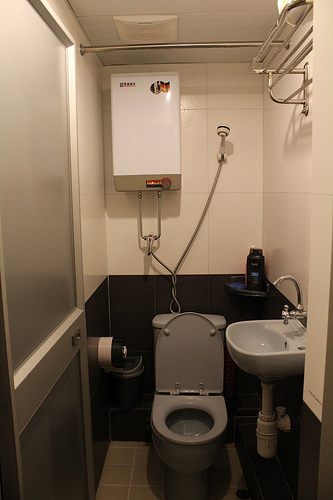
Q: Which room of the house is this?
A: It is a bathroom.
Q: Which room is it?
A: It is a bathroom.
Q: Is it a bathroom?
A: Yes, it is a bathroom.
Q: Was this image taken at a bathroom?
A: Yes, it was taken in a bathroom.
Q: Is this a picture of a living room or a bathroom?
A: It is showing a bathroom.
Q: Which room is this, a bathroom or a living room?
A: It is a bathroom.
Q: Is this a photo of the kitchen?
A: No, the picture is showing the bathroom.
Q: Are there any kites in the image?
A: No, there are no kites.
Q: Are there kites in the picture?
A: No, there are no kites.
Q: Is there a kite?
A: No, there are no kites.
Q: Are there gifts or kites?
A: No, there are no kites or gifts.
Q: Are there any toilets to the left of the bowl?
A: Yes, there is a toilet to the left of the bowl.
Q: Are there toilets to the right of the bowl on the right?
A: No, the toilet is to the left of the bowl.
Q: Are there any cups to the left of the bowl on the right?
A: No, there is a toilet to the left of the bowl.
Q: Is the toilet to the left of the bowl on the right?
A: Yes, the toilet is to the left of the bowl.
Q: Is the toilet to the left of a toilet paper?
A: No, the toilet is to the left of the bowl.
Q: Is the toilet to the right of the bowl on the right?
A: No, the toilet is to the left of the bowl.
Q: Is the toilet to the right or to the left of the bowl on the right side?
A: The toilet is to the left of the bowl.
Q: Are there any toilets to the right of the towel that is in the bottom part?
A: Yes, there is a toilet to the right of the towel.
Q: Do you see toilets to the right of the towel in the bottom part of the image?
A: Yes, there is a toilet to the right of the towel.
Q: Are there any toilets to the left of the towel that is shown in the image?
A: No, the toilet is to the right of the towel.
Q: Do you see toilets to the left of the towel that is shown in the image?
A: No, the toilet is to the right of the towel.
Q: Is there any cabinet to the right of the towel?
A: No, there is a toilet to the right of the towel.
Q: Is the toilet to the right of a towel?
A: Yes, the toilet is to the right of a towel.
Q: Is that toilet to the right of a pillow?
A: No, the toilet is to the right of a towel.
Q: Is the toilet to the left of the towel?
A: No, the toilet is to the right of the towel.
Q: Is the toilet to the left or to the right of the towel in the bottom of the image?
A: The toilet is to the right of the towel.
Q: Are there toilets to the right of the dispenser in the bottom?
A: Yes, there is a toilet to the right of the dispenser.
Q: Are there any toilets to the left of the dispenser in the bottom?
A: No, the toilet is to the right of the dispenser.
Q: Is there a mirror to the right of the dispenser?
A: No, there is a toilet to the right of the dispenser.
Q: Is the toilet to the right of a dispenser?
A: Yes, the toilet is to the right of a dispenser.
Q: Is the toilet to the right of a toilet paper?
A: No, the toilet is to the right of a dispenser.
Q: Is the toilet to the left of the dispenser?
A: No, the toilet is to the right of the dispenser.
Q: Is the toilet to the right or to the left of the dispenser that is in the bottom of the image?
A: The toilet is to the right of the dispenser.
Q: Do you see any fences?
A: No, there are no fences.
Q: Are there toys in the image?
A: No, there are no toys.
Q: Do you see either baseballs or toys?
A: No, there are no toys or baseballs.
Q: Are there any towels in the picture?
A: Yes, there is a towel.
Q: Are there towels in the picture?
A: Yes, there is a towel.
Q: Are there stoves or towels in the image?
A: Yes, there is a towel.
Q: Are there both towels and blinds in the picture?
A: No, there is a towel but no blinds.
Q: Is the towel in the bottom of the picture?
A: Yes, the towel is in the bottom of the image.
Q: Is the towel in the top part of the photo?
A: No, the towel is in the bottom of the image.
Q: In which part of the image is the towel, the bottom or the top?
A: The towel is in the bottom of the image.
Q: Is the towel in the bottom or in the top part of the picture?
A: The towel is in the bottom of the image.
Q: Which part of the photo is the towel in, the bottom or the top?
A: The towel is in the bottom of the image.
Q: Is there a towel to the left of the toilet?
A: Yes, there is a towel to the left of the toilet.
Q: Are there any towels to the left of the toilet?
A: Yes, there is a towel to the left of the toilet.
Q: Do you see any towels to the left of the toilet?
A: Yes, there is a towel to the left of the toilet.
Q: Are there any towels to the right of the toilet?
A: No, the towel is to the left of the toilet.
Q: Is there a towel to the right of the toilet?
A: No, the towel is to the left of the toilet.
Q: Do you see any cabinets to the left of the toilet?
A: No, there is a towel to the left of the toilet.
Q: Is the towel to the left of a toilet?
A: Yes, the towel is to the left of a toilet.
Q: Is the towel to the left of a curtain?
A: No, the towel is to the left of a toilet.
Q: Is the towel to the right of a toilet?
A: No, the towel is to the left of a toilet.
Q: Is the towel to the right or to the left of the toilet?
A: The towel is to the left of the toilet.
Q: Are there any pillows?
A: No, there are no pillows.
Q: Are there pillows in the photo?
A: No, there are no pillows.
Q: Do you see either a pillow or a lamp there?
A: No, there are no pillows or lamps.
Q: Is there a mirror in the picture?
A: No, there are no mirrors.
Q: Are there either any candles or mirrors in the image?
A: No, there are no mirrors or candles.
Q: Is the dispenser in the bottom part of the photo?
A: Yes, the dispenser is in the bottom of the image.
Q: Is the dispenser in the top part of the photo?
A: No, the dispenser is in the bottom of the image.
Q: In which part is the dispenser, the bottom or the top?
A: The dispenser is in the bottom of the image.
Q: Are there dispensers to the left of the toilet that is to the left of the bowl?
A: Yes, there is a dispenser to the left of the toilet.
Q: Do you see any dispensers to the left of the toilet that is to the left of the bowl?
A: Yes, there is a dispenser to the left of the toilet.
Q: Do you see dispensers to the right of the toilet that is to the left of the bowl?
A: No, the dispenser is to the left of the toilet.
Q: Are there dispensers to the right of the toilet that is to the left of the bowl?
A: No, the dispenser is to the left of the toilet.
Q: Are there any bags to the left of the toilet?
A: No, there is a dispenser to the left of the toilet.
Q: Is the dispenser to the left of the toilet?
A: Yes, the dispenser is to the left of the toilet.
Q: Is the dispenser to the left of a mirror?
A: No, the dispenser is to the left of the toilet.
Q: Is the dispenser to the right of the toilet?
A: No, the dispenser is to the left of the toilet.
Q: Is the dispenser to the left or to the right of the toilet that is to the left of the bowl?
A: The dispenser is to the left of the toilet.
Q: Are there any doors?
A: Yes, there is a door.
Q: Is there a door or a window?
A: Yes, there is a door.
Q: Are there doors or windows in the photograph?
A: Yes, there is a door.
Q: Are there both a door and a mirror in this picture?
A: No, there is a door but no mirrors.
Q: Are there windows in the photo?
A: No, there are no windows.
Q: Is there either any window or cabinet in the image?
A: No, there are no windows or cabinets.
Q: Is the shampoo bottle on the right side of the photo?
A: Yes, the shampoo bottle is on the right of the image.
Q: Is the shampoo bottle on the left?
A: No, the shampoo bottle is on the right of the image.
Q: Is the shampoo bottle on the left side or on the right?
A: The shampoo bottle is on the right of the image.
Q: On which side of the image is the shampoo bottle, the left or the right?
A: The shampoo bottle is on the right of the image.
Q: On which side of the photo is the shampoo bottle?
A: The shampoo bottle is on the right of the image.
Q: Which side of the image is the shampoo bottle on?
A: The shampoo bottle is on the right of the image.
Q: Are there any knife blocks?
A: No, there are no knife blocks.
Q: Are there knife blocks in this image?
A: No, there are no knife blocks.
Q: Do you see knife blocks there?
A: No, there are no knife blocks.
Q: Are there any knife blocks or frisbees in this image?
A: No, there are no knife blocks or frisbees.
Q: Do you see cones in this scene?
A: No, there are no cones.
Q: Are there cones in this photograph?
A: No, there are no cones.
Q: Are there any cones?
A: No, there are no cones.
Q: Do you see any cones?
A: No, there are no cones.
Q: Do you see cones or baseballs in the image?
A: No, there are no cones or baseballs.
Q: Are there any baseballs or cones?
A: No, there are no cones or baseballs.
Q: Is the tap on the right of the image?
A: Yes, the tap is on the right of the image.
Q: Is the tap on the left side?
A: No, the tap is on the right of the image.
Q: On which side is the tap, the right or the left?
A: The tap is on the right of the image.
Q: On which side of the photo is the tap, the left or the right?
A: The tap is on the right of the image.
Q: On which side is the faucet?
A: The faucet is on the right of the image.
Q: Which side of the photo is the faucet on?
A: The faucet is on the right of the image.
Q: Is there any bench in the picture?
A: No, there are no benches.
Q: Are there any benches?
A: No, there are no benches.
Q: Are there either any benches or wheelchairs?
A: No, there are no benches or wheelchairs.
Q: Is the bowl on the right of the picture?
A: Yes, the bowl is on the right of the image.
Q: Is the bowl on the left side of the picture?
A: No, the bowl is on the right of the image.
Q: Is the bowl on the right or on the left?
A: The bowl is on the right of the image.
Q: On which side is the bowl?
A: The bowl is on the right of the image.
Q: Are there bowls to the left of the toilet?
A: No, the bowl is to the right of the toilet.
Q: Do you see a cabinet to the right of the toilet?
A: No, there is a bowl to the right of the toilet.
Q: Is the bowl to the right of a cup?
A: No, the bowl is to the right of the toilet.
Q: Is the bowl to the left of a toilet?
A: No, the bowl is to the right of a toilet.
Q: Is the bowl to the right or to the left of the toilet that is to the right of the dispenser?
A: The bowl is to the right of the toilet.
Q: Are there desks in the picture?
A: No, there are no desks.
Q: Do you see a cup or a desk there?
A: No, there are no desks or cups.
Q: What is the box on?
A: The box is on the wall.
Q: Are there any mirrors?
A: No, there are no mirrors.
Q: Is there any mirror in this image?
A: No, there are no mirrors.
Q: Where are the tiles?
A: The tiles are on the floor.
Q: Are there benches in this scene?
A: No, there are no benches.